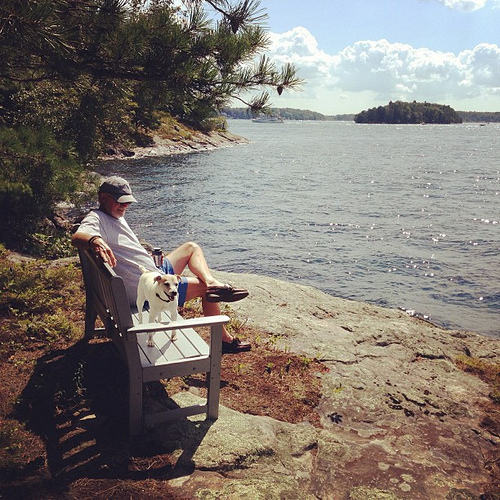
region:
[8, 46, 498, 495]
Exterior shot, during warm weather, daylight hours.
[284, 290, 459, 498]
Semi-rocky terrain.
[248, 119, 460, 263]
Large body of deep blue, glistening water.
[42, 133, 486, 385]
Natural, uneven harbor area.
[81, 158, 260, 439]
Bench with man and dog.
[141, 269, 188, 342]
Small, white dog with tan areas on muzzle.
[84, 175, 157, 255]
Male with white tee and cap, overshadowing face.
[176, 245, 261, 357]
Pale leg crossed over knee.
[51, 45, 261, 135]
Overhanging branches of evergreen tree.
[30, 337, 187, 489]
Shadow of bench, showing slats.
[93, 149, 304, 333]
man on wooden bench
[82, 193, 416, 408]
man looking at dog on bench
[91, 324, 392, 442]
wooden bench on rocky ground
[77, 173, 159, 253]
man in baseball hat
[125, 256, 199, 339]
small white dog on bench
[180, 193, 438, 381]
water's edge is near bench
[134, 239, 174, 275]
man holding drink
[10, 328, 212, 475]
shadow of bench is behind it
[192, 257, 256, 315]
man by water's edge with no socks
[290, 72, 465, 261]
lake with green island in distance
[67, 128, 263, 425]
man and dog on a bench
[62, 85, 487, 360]
bench overlooking a large lake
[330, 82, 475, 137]
island covered with trees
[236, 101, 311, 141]
boat floating on the water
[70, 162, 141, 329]
man resting arm across the bench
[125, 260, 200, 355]
dog standing and facing arm rest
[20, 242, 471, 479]
bench on soil and wide rocks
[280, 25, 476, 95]
large puffy cloud in blue sky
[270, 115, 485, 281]
water glistening in bright sunlight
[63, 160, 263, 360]
man looking down at dog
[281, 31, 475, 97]
Fluffy, white clouds on porcelain blue sky.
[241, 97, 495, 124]
Distant hills and islet.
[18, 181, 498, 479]
Bare, rocky area with white, elderly wooden bench.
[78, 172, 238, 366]
Person and dog, resting on bench.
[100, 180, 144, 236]
Person with cap, looking down on dog.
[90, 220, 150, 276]
White tee-shirt with natural wrinkles.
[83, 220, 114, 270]
Right arm, extended over back of bench.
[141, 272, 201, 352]
Dog, facing forward.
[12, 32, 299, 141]
Branch with pine needles, overlooking bench.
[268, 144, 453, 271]
Calm, blue body of water.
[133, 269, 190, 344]
white dog with brown ears and face standing on bench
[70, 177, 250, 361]
man dressed for warm weather sitting on bench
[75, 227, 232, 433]
wooden bench on the edge of a body of water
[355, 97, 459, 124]
small island in middle of lake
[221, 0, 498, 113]
blue sky with white fluffy clouds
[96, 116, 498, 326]
large lake with deep blue water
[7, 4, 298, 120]
evergreen branch overhanging the lake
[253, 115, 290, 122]
boat in the distance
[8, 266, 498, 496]
rocky shore extending into the lake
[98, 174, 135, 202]
khaki ball cap